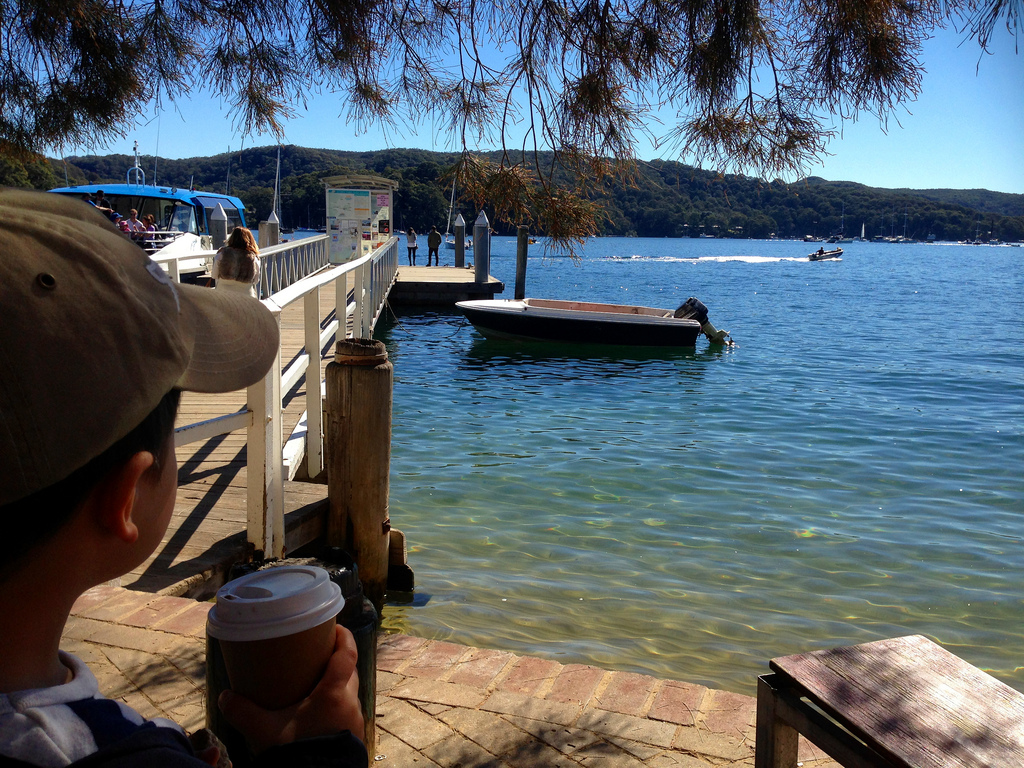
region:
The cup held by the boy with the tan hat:
[210, 565, 344, 721]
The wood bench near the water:
[728, 603, 1019, 765]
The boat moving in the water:
[801, 238, 858, 264]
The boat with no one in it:
[447, 278, 738, 368]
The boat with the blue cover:
[52, 167, 267, 273]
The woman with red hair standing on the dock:
[206, 216, 267, 318]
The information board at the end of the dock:
[310, 162, 397, 274]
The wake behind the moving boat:
[586, 244, 821, 276]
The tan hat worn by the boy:
[0, 180, 285, 517]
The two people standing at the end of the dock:
[392, 216, 446, 267]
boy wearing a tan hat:
[0, 186, 367, 766]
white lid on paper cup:
[206, 563, 349, 744]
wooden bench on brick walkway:
[69, 581, 1022, 766]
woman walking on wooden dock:
[141, 221, 405, 596]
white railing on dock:
[141, 227, 407, 560]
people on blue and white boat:
[46, 170, 263, 287]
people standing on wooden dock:
[391, 217, 503, 301]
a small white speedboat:
[462, 291, 719, 358]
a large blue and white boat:
[57, 168, 250, 283]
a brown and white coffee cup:
[204, 568, 342, 721]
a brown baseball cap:
[2, 179, 284, 494]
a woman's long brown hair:
[213, 228, 262, 285]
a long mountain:
[80, 141, 1022, 255]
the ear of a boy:
[99, 456, 154, 546]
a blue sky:
[160, 42, 1006, 183]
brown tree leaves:
[454, 2, 818, 253]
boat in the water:
[394, 243, 755, 469]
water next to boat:
[486, 372, 785, 537]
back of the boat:
[599, 255, 755, 415]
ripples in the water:
[597, 417, 857, 542]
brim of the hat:
[163, 227, 353, 428]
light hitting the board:
[857, 617, 1010, 744]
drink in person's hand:
[164, 522, 371, 742]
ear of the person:
[65, 426, 176, 578]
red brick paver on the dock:
[694, 690, 753, 726]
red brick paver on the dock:
[645, 659, 696, 730]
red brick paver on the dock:
[590, 656, 647, 718]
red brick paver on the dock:
[542, 646, 597, 710]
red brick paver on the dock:
[497, 653, 546, 704]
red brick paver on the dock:
[453, 631, 510, 688]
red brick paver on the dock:
[397, 656, 452, 682]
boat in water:
[438, 270, 830, 388]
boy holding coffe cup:
[207, 509, 379, 762]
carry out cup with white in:
[197, 556, 379, 766]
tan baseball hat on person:
[1, 180, 287, 497]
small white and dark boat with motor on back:
[446, 287, 740, 370]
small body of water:
[253, 222, 1021, 717]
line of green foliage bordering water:
[57, 137, 1022, 245]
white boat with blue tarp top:
[43, 173, 256, 290]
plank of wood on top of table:
[759, 623, 1020, 766]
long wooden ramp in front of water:
[109, 162, 511, 603]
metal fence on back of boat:
[119, 218, 184, 258]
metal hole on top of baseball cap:
[24, 262, 66, 304]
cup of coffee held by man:
[222, 575, 344, 697]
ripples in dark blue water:
[454, 397, 550, 461]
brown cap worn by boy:
[5, 205, 291, 418]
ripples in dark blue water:
[505, 498, 589, 563]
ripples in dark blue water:
[710, 461, 806, 532]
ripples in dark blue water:
[804, 388, 894, 442]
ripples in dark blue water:
[855, 298, 961, 350]